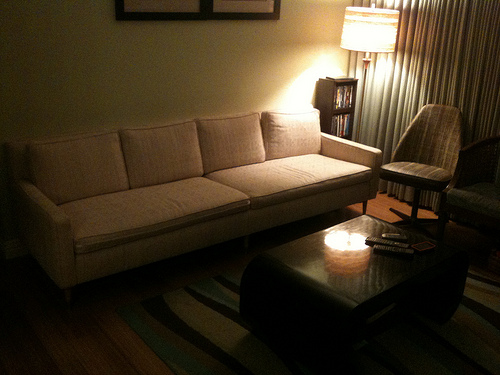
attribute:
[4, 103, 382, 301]
couch — light colored, white, small, four seater, empty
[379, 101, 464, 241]
chair — armless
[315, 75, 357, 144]
bookshelf — small, wooden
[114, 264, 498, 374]
rug — multicolored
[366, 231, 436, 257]
remote controls — black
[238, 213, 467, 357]
coffee table — dark colored, small, dark, black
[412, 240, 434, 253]
tablet — red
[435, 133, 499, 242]
armchair — black, brown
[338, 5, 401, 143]
floor lamp — tall, on, standing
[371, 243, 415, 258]
remote control — black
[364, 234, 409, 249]
remote control — black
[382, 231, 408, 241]
remote control — black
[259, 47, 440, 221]
light — dim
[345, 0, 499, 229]
curtains — shut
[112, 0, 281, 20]
picture frame — brown, wooden